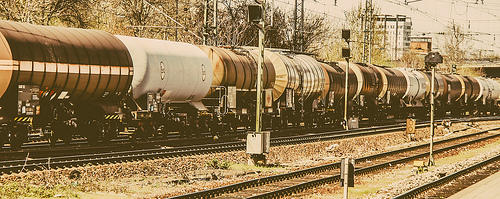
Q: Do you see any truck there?
A: No, there are no trucks.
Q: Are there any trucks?
A: No, there are no trucks.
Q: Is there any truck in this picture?
A: No, there are no trucks.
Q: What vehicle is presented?
A: The vehicle is a car.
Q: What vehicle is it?
A: The vehicle is a car.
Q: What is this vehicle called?
A: This is a car.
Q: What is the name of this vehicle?
A: This is a car.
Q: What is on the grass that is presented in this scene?
A: The car is on the grass.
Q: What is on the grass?
A: The car is on the grass.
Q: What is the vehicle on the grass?
A: The vehicle is a car.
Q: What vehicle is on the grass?
A: The vehicle is a car.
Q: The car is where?
A: The car is on the grass.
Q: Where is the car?
A: The car is on the grass.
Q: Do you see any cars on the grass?
A: Yes, there is a car on the grass.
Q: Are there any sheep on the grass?
A: No, there is a car on the grass.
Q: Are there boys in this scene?
A: No, there are no boys.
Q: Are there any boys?
A: No, there are no boys.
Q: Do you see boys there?
A: No, there are no boys.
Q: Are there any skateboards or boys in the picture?
A: No, there are no boys or skateboards.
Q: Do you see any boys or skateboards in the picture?
A: No, there are no boys or skateboards.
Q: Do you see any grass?
A: Yes, there is grass.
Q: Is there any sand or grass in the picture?
A: Yes, there is grass.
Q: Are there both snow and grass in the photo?
A: No, there is grass but no snow.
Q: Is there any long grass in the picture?
A: Yes, there is long grass.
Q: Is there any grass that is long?
A: Yes, there is grass that is long.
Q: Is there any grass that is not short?
A: Yes, there is long grass.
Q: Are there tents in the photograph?
A: No, there are no tents.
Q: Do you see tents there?
A: No, there are no tents.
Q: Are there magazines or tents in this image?
A: No, there are no tents or magazines.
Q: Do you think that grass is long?
A: Yes, the grass is long.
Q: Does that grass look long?
A: Yes, the grass is long.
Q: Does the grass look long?
A: Yes, the grass is long.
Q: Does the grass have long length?
A: Yes, the grass is long.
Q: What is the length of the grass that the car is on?
A: The grass is long.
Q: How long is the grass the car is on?
A: The grass is long.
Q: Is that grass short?
A: No, the grass is long.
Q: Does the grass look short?
A: No, the grass is long.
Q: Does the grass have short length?
A: No, the grass is long.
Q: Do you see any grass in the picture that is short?
A: No, there is grass but it is long.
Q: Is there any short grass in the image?
A: No, there is grass but it is long.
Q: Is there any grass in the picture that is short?
A: No, there is grass but it is long.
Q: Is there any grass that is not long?
A: No, there is grass but it is long.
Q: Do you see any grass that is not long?
A: No, there is grass but it is long.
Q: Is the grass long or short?
A: The grass is long.